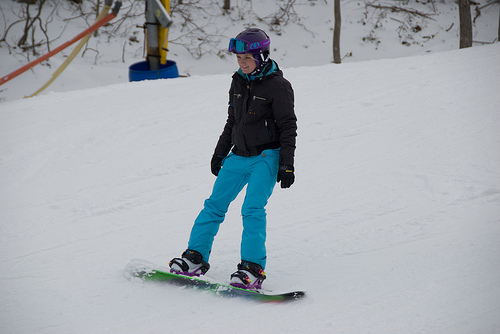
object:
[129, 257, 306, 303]
snowboard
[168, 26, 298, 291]
girl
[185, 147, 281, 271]
pants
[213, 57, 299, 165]
jacket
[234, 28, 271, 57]
helmet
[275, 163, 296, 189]
gloves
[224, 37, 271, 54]
goggles